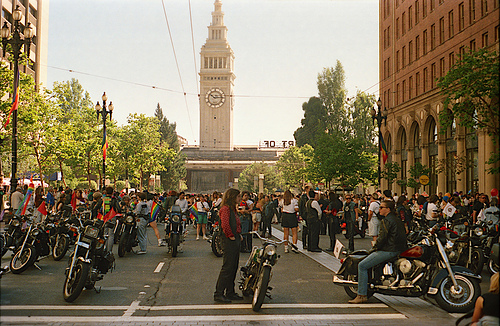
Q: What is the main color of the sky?
A: Blue.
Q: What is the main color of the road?
A: Gray.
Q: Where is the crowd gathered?
A: In the street.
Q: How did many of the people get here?
A: Motorcycle.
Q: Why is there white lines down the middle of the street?
A: To divide the lanes.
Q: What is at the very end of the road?
A: A clock tower.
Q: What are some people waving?
A: Flags.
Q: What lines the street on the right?
A: Trees.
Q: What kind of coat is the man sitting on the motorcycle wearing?
A: A leather jacket.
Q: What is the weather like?
A: Overcast and cool.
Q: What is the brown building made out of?
A: Brick.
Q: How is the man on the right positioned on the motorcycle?
A: He is sitting backwards.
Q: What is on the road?
A: Motorcycles.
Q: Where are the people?
A: The road and the sidewalk.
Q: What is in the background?
A: A clock tower.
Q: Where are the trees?
A: On the sidewalk.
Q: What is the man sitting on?
A: A motorcycle.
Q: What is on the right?
A: A tall building.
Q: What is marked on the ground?
A: A crosswalk.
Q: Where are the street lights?
A: On the sidewalks by the trees.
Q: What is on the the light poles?
A: Flags.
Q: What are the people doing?
A: Standing around.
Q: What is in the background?
A: A clock tower.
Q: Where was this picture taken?
A: In the city.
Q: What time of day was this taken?
A: Daytime.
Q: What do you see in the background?
A: Tall buildings.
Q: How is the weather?
A: Sunny and warm.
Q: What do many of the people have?
A: Motorcycles.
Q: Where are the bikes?
A: Parked in the street.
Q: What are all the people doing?
A: Gathering in the street.